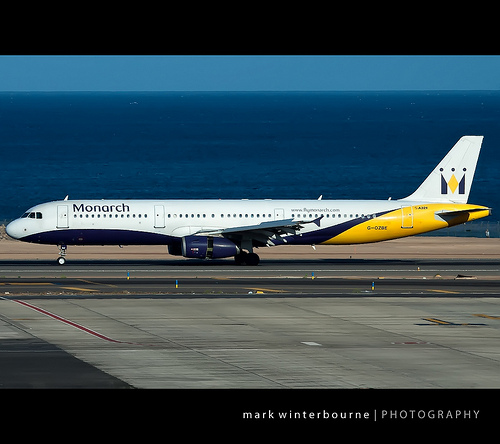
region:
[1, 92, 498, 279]
jetliner on runway in front of large body of water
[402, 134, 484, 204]
tail of commercial jet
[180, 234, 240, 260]
left engine of jet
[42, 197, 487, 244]
body of commercial jet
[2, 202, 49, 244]
nose of jet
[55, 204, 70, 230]
front exit door of jet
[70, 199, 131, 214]
"Monarch" printed on side of jet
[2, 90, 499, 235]
ocean behind white, yellow and blue jet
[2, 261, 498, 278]
airport runway with white line down the middle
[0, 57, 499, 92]
clear sky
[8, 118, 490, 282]
large airplane on tarmac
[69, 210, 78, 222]
window on side of plane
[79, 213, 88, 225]
window on side of plane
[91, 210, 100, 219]
window on side of plane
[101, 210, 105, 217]
window on side of plane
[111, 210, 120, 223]
window on side of plane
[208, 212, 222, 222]
window on side of plane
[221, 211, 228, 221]
window on side of plane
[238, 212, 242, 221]
window on side of plane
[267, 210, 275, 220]
window on side of plane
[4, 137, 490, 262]
yellow, blue and white airplane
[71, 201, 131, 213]
the word monarch on the side of the plane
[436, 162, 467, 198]
symbol on the tail of the plane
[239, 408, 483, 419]
white text on the bottom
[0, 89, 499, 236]
ocean water seen in the background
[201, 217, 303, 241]
left wing of the airplane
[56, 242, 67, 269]
front wheel of the airplane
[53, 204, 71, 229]
front side door of the airplane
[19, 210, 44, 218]
windows on the front of the plane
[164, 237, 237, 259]
engine of the airplane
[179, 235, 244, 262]
a large blue engine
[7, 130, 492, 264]
a monarch commercial airliner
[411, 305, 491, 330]
colorful stripes on the tarmac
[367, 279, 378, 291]
a short blue and yellow post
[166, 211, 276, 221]
a row of small windows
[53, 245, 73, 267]
a plane's front landing gear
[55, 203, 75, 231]
a small metal door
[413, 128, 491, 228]
the tail of a plane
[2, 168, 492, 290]
a runway by the ocean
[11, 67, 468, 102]
a clear horizon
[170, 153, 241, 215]
airplane next to the water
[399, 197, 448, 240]
plane is yellow in the back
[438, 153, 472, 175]
three blue dots on the tail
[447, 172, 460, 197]
yellow diamond on the tail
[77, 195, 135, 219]
Monarch is written on the plane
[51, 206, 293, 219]
three doors on the airplane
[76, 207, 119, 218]
passenger windows on the plane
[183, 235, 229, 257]
plane engine is blue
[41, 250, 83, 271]
wheel on the airplane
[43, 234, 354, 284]
airplane is on the tarmac